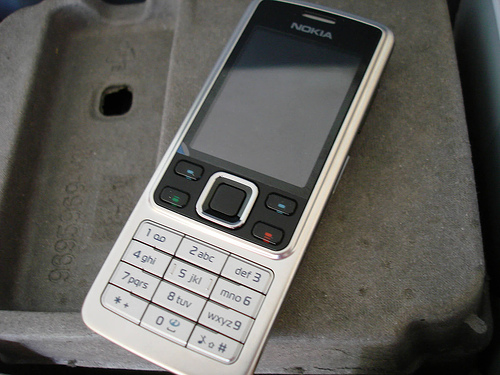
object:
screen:
[174, 0, 384, 200]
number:
[48, 181, 89, 282]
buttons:
[119, 239, 172, 278]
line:
[172, 195, 180, 203]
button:
[160, 187, 190, 208]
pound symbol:
[218, 342, 227, 353]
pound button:
[186, 325, 245, 365]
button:
[173, 236, 229, 275]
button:
[162, 258, 218, 298]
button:
[209, 277, 264, 319]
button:
[138, 303, 195, 346]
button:
[194, 170, 258, 230]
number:
[146, 228, 152, 237]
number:
[189, 245, 198, 255]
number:
[167, 291, 176, 300]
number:
[253, 272, 262, 282]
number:
[133, 250, 141, 258]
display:
[184, 22, 360, 188]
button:
[185, 323, 244, 364]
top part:
[249, 2, 395, 42]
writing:
[291, 21, 333, 40]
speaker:
[303, 13, 336, 24]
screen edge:
[309, 14, 396, 206]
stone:
[403, 180, 447, 234]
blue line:
[183, 170, 193, 172]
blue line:
[277, 203, 285, 208]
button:
[174, 161, 204, 181]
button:
[265, 193, 298, 216]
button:
[252, 221, 284, 246]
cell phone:
[80, 0, 395, 375]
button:
[220, 256, 273, 295]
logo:
[291, 21, 332, 38]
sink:
[0, 0, 500, 375]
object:
[0, 0, 176, 313]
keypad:
[99, 219, 275, 366]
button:
[133, 220, 183, 255]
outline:
[188, 167, 268, 236]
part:
[226, 127, 242, 144]